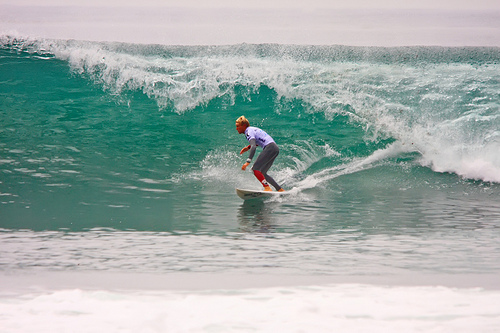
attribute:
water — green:
[57, 120, 195, 209]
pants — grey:
[251, 141, 282, 193]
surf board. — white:
[218, 167, 310, 207]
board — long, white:
[237, 187, 278, 199]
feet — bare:
[258, 181, 297, 198]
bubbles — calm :
[2, 228, 499, 294]